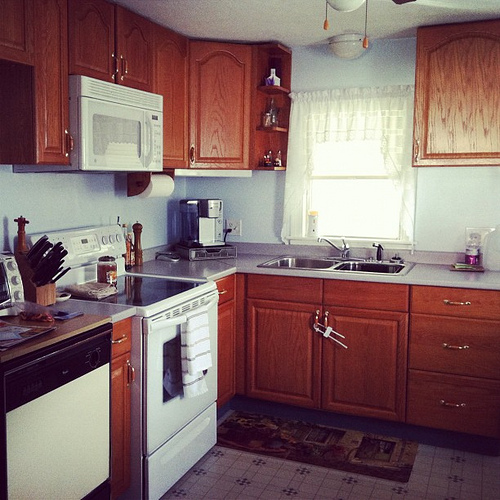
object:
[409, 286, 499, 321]
drawer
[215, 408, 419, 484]
mat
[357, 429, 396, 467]
windows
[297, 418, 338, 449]
windows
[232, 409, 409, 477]
houses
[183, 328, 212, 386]
stripes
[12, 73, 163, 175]
microwave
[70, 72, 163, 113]
vent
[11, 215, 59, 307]
knife block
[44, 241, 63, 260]
knives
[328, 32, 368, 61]
ceiling fan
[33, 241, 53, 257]
knives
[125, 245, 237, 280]
counter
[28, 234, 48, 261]
knives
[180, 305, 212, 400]
cloth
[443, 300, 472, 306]
handle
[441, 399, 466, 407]
handle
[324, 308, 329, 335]
handle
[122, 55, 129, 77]
handle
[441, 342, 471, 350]
handle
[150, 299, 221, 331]
handle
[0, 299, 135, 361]
counter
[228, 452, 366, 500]
ground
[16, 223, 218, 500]
stove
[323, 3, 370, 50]
cords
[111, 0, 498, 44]
ceiling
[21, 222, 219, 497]
dish washer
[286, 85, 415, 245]
window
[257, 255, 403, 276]
sink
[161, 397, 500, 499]
floor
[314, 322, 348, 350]
lock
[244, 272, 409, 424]
cabinet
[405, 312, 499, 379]
drawer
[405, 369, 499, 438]
drawer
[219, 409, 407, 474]
runner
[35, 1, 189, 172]
cabinets